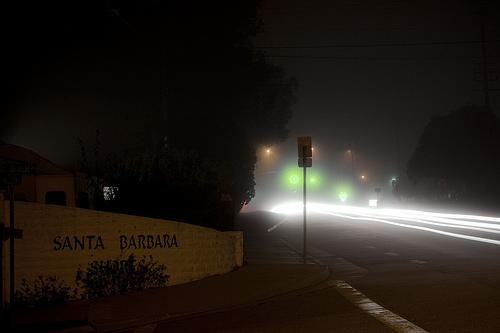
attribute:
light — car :
[273, 197, 498, 244]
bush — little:
[62, 239, 183, 309]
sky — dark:
[268, 49, 438, 217]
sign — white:
[5, 186, 251, 314]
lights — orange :
[274, 168, 329, 188]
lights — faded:
[283, 156, 333, 193]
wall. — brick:
[25, 234, 39, 279]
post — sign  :
[278, 129, 330, 247]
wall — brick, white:
[35, 212, 175, 281]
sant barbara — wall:
[34, 222, 211, 258]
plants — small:
[74, 256, 176, 327]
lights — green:
[282, 157, 362, 207]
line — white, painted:
[336, 281, 406, 331]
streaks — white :
[268, 199, 495, 251]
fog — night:
[256, 135, 439, 226]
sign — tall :
[283, 127, 320, 269]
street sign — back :
[296, 134, 314, 261]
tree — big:
[95, 15, 259, 218]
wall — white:
[12, 204, 254, 284]